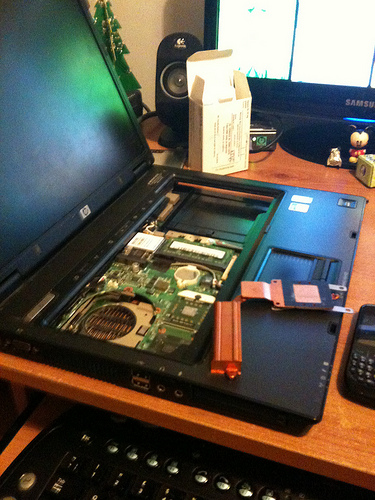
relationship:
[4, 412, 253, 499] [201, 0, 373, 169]
keyboard used by computer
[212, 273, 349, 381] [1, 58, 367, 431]
device on laptop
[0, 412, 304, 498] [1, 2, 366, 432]
keyboard beneath laptop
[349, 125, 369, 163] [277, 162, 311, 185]
mickey mouse on desk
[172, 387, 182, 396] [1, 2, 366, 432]
jack on laptop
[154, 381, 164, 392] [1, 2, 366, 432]
jack on laptop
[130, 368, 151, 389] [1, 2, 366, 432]
jack on laptop